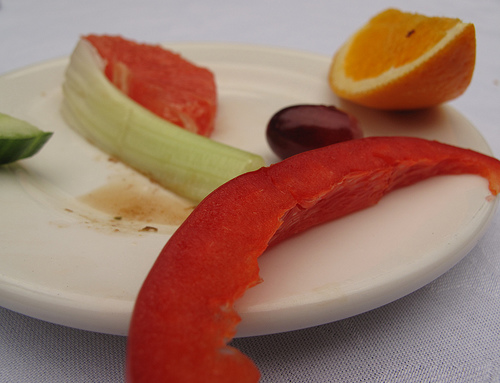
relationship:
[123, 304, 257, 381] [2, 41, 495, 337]
food hangs off plate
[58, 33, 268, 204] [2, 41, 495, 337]
celery on plate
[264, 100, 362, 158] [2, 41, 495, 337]
food sitting on plate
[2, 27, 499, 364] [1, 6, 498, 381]
plate of food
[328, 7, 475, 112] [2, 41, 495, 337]
orange on plate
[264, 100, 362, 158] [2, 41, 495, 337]
food on plate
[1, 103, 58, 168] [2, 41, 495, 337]
cucumber on plate